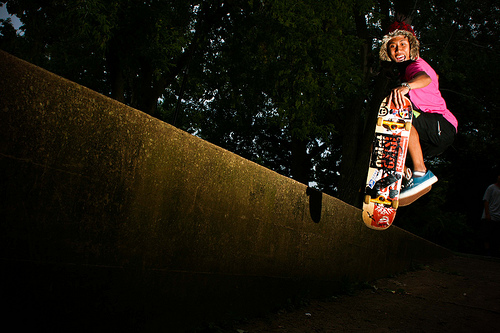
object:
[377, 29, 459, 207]
skateboarder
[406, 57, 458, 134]
shirt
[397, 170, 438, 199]
shoes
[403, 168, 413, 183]
laces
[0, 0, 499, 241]
trees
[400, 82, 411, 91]
watch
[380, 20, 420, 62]
hat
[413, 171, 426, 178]
sock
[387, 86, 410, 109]
hand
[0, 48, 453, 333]
wall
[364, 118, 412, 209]
wheels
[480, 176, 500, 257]
person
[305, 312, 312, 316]
trash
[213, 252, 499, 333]
ground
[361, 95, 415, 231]
stickers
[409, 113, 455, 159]
shorts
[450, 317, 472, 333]
leaves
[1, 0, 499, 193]
sky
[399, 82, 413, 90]
wrist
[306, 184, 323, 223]
shadow